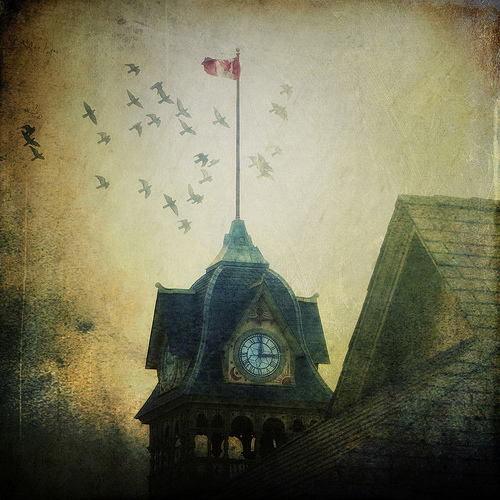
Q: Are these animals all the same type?
A: Yes, all the animals are birds.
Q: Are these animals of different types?
A: No, all the animals are birds.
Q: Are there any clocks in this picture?
A: Yes, there is a clock.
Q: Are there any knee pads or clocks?
A: Yes, there is a clock.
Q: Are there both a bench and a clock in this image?
A: No, there is a clock but no benches.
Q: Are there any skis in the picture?
A: No, there are no skis.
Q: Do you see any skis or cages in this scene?
A: No, there are no skis or cages.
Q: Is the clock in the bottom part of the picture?
A: Yes, the clock is in the bottom of the image.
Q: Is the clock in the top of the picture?
A: No, the clock is in the bottom of the image.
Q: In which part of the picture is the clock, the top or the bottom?
A: The clock is in the bottom of the image.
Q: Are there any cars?
A: No, there are no cars.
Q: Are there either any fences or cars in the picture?
A: No, there are no cars or fences.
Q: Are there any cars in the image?
A: No, there are no cars.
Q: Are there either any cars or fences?
A: No, there are no cars or fences.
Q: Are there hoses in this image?
A: No, there are no hoses.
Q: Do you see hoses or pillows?
A: No, there are no hoses or pillows.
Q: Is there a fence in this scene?
A: No, there are no fences.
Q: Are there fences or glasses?
A: No, there are no fences or glasses.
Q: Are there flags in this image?
A: Yes, there is a flag.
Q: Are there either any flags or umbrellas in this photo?
A: Yes, there is a flag.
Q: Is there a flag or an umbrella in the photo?
A: Yes, there is a flag.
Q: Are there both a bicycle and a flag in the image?
A: No, there is a flag but no bicycles.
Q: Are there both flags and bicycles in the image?
A: No, there is a flag but no bicycles.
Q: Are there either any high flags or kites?
A: Yes, there is a high flag.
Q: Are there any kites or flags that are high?
A: Yes, the flag is high.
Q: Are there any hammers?
A: No, there are no hammers.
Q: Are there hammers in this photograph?
A: No, there are no hammers.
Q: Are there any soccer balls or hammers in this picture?
A: No, there are no hammers or soccer balls.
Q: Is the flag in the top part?
A: Yes, the flag is in the top of the image.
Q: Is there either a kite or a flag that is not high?
A: No, there is a flag but it is high.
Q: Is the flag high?
A: Yes, the flag is high.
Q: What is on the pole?
A: The flag is on the pole.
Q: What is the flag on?
A: The flag is on the pole.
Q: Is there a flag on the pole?
A: Yes, there is a flag on the pole.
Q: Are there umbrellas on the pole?
A: No, there is a flag on the pole.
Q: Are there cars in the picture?
A: No, there are no cars.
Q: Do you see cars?
A: No, there are no cars.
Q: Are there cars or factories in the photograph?
A: No, there are no cars or factories.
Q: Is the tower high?
A: Yes, the tower is high.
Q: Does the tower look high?
A: Yes, the tower is high.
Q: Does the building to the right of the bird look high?
A: Yes, the tower is high.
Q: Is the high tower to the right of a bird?
A: Yes, the tower is to the right of a bird.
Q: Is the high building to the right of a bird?
A: Yes, the tower is to the right of a bird.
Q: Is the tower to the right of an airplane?
A: No, the tower is to the right of a bird.